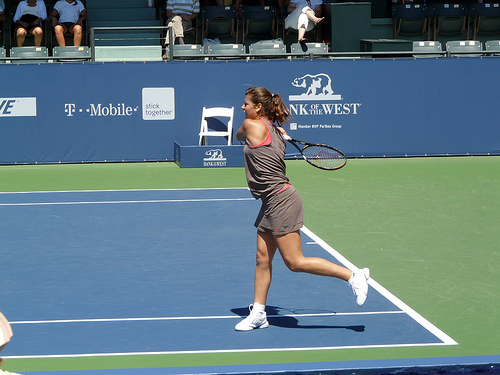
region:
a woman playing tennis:
[234, 86, 370, 327]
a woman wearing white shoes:
[236, 265, 368, 332]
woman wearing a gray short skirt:
[253, 185, 303, 233]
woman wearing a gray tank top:
[243, 120, 288, 199]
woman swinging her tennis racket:
[237, 84, 369, 338]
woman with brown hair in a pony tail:
[240, 85, 289, 125]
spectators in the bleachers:
[1, 1, 331, 45]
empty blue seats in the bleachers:
[391, 0, 498, 43]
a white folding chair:
[196, 105, 234, 146]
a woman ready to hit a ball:
[233, 88, 370, 337]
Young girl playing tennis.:
[228, 81, 375, 342]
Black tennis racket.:
[280, 92, 366, 195]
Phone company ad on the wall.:
[45, 86, 147, 136]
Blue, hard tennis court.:
[2, 160, 329, 373]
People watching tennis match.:
[3, 0, 93, 56]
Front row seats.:
[165, 28, 376, 73]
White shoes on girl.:
[207, 262, 392, 344]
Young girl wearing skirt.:
[243, 170, 378, 340]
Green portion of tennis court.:
[355, 161, 498, 329]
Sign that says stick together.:
[131, 75, 193, 142]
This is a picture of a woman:
[217, 90, 350, 371]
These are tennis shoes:
[213, 280, 307, 368]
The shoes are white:
[218, 295, 311, 368]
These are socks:
[243, 293, 273, 310]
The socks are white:
[228, 288, 272, 311]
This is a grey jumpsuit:
[243, 137, 332, 259]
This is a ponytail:
[231, 74, 322, 131]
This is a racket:
[313, 105, 384, 242]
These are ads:
[41, 97, 187, 183]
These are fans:
[32, 5, 153, 73]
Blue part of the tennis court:
[76, 238, 111, 273]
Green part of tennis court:
[356, 199, 396, 236]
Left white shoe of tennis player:
[349, 268, 371, 306]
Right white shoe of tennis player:
[237, 305, 273, 340]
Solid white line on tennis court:
[88, 307, 155, 337]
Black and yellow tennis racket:
[299, 135, 348, 175]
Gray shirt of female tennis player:
[253, 151, 278, 179]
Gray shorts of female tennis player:
[271, 201, 296, 228]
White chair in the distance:
[195, 104, 235, 143]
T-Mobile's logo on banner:
[63, 95, 135, 127]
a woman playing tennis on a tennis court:
[230, 82, 375, 335]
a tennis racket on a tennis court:
[275, 126, 357, 174]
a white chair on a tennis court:
[192, 100, 236, 153]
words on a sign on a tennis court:
[54, 98, 143, 125]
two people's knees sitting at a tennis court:
[7, 18, 87, 55]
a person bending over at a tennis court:
[276, 4, 329, 48]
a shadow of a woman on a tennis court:
[265, 293, 371, 339]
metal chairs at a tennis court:
[408, 37, 498, 66]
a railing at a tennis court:
[84, 20, 180, 66]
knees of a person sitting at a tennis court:
[163, 2, 206, 59]